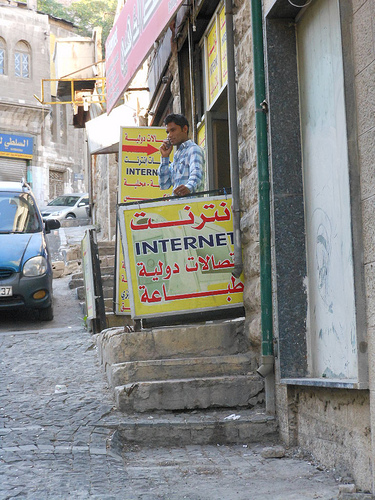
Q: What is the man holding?
A: A phone.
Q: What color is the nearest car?
A: Blue.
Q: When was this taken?
A: During the day.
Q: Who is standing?
A: A man.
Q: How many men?
A: One.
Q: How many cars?
A: Two.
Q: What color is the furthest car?
A: Silver.